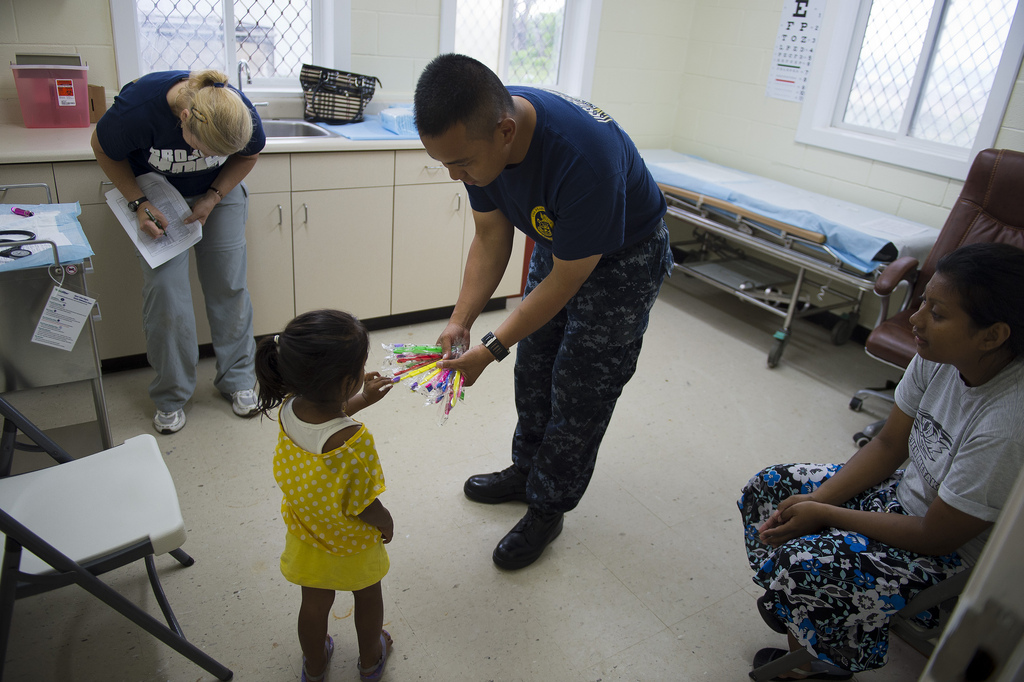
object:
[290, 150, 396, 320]
cabinet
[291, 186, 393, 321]
door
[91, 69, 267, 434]
woman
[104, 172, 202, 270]
paper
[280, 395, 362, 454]
undershirt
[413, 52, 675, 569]
man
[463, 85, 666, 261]
shirt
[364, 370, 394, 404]
girl's hand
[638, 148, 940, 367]
bed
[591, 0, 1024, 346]
wall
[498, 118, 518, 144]
left ear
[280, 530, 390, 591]
skirt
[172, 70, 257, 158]
hair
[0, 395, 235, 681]
chair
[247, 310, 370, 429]
hair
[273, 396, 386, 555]
shirt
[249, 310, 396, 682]
child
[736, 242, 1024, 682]
woman